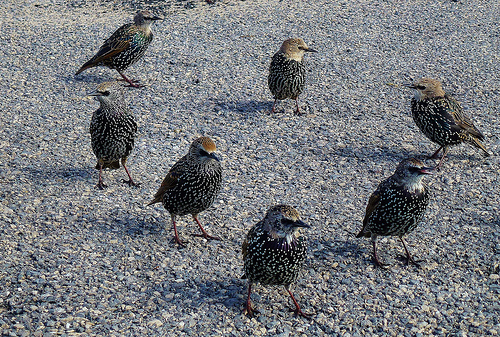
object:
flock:
[60, 26, 465, 269]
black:
[297, 41, 318, 57]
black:
[400, 79, 424, 94]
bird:
[397, 66, 491, 150]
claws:
[266, 94, 308, 119]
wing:
[75, 34, 121, 76]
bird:
[71, 9, 173, 83]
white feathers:
[254, 220, 288, 239]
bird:
[235, 202, 316, 322]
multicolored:
[91, 108, 140, 160]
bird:
[82, 94, 142, 190]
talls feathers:
[159, 164, 224, 211]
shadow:
[211, 97, 273, 119]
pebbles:
[259, 129, 319, 167]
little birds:
[106, 20, 479, 131]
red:
[272, 54, 304, 87]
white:
[381, 176, 419, 227]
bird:
[354, 156, 437, 269]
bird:
[263, 35, 311, 111]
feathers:
[267, 59, 313, 91]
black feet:
[264, 90, 311, 117]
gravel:
[241, 129, 296, 161]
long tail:
[459, 120, 489, 164]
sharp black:
[397, 82, 422, 96]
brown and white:
[425, 76, 458, 129]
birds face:
[409, 78, 436, 98]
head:
[257, 20, 328, 68]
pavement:
[12, 0, 499, 267]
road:
[336, 96, 377, 138]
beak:
[306, 42, 329, 56]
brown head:
[280, 34, 317, 57]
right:
[273, 33, 326, 66]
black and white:
[259, 195, 433, 270]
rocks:
[367, 20, 411, 52]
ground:
[358, 14, 446, 42]